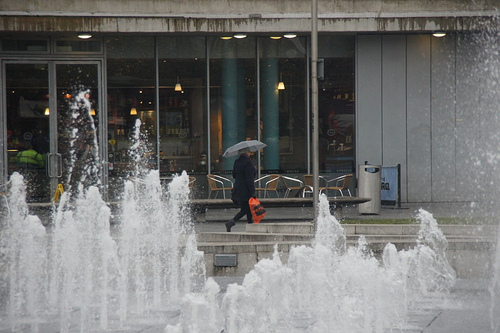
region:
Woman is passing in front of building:
[206, 114, 295, 234]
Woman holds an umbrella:
[213, 131, 276, 238]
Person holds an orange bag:
[213, 131, 283, 238]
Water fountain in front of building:
[8, 108, 458, 332]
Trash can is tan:
[350, 154, 386, 217]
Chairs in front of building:
[206, 164, 353, 211]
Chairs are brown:
[204, 164, 360, 213]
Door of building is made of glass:
[3, 44, 117, 229]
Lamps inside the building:
[23, 46, 300, 133]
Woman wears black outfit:
[217, 134, 272, 232]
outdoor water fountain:
[298, 185, 381, 331]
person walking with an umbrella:
[215, 136, 289, 236]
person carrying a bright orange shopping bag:
[217, 125, 282, 234]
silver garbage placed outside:
[351, 156, 396, 217]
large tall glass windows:
[105, 36, 225, 214]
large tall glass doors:
[2, 60, 98, 203]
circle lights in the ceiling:
[71, 30, 465, 48]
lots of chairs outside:
[179, 163, 361, 195]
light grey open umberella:
[218, 137, 273, 164]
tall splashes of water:
[53, 67, 118, 331]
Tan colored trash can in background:
[353, 156, 391, 226]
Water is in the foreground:
[6, 163, 463, 332]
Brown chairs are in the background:
[180, 159, 358, 204]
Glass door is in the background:
[0, 53, 125, 213]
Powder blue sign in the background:
[358, 157, 420, 204]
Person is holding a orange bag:
[239, 193, 282, 238]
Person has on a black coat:
[217, 153, 277, 220]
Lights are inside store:
[168, 76, 299, 101]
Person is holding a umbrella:
[217, 122, 268, 178]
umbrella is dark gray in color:
[210, 131, 283, 187]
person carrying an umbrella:
[216, 129, 290, 240]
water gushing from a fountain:
[18, 86, 490, 331]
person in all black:
[213, 138, 273, 230]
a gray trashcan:
[357, 151, 389, 228]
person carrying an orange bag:
[226, 134, 276, 232]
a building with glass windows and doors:
[1, 53, 391, 197]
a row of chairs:
[197, 160, 360, 206]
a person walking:
[218, 137, 273, 243]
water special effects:
[5, 178, 462, 271]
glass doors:
[1, 58, 108, 209]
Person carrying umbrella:
[206, 124, 273, 241]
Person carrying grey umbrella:
[210, 124, 282, 257]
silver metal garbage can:
[345, 140, 386, 229]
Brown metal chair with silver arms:
[320, 158, 355, 208]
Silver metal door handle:
[42, 144, 72, 190]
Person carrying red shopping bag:
[205, 128, 278, 254]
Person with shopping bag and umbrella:
[189, 112, 286, 262]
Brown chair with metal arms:
[272, 164, 306, 208]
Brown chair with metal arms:
[198, 158, 240, 220]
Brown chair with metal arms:
[248, 161, 288, 202]